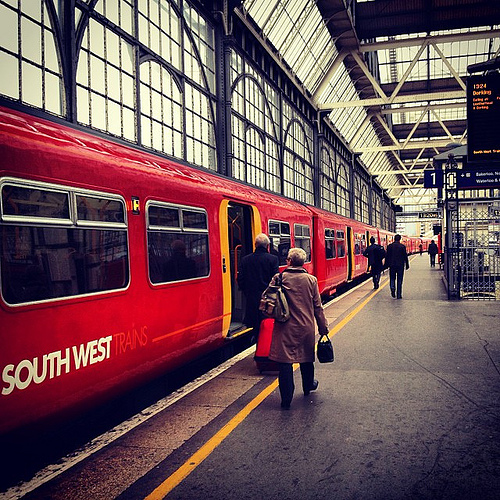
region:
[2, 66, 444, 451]
a long red train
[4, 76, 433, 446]
a red and yellow train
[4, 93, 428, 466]
a train stopping in a station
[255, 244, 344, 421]
a lady holding a red shopping bag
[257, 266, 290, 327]
a grey backpack on the lady's back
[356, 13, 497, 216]
the see through glass ceiling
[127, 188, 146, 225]
the small light in between the train's windows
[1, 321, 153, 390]
the train's logo on the side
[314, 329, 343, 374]
The lady's black handbag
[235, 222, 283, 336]
the man slightly ahead of the woman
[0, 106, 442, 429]
the train is bright red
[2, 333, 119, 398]
the train has white lettering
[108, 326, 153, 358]
the train has red lettering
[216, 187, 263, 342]
the train has yellow doors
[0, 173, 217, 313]
the train has black windows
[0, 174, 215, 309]
the windows are framed in silver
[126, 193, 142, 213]
there is a light on the side of the train that says R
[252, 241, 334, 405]
an old lady carrying three bags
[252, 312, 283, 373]
the bag is red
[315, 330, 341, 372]
the bag is black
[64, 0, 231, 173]
train station window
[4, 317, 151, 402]
train says south west trains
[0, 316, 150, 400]
the lettering on the train is white and red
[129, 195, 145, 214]
the train has a capital letter R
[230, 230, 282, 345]
the man is getting on the train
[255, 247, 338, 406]
the woman is old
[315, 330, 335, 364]
the woman is carrying a black bag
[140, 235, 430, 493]
there's a yellow line on the train station floor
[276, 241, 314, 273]
the head of a woman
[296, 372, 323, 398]
a black shoe on the woman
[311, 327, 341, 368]
a small black bag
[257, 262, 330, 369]
a brown coat on a person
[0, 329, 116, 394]
white writing on the train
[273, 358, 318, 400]
a pair of black pants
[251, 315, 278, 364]
a red bag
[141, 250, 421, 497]
a yellow line on the ground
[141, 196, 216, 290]
a window on the train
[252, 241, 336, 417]
a woman on the sidewalk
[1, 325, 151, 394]
name of company on the train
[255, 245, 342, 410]
woman walking with a bag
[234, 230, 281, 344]
man with a dark blue jacket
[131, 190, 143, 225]
light between windows on the train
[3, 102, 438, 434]
long red passenger train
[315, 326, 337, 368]
bag in woman's right hand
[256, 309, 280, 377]
red rolling bag pulled by man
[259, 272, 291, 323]
shoulder bags on woman's left shoulder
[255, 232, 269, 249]
balding head of man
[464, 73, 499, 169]
digital train schedule